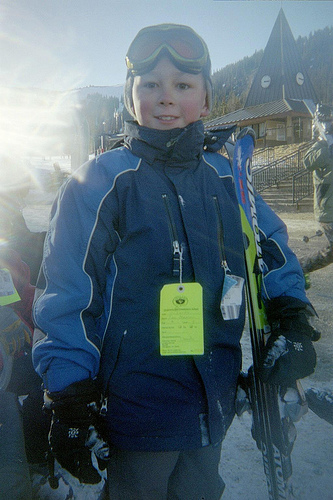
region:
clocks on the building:
[262, 71, 322, 92]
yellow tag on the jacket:
[147, 239, 212, 363]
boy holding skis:
[220, 128, 322, 419]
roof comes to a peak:
[251, 15, 327, 103]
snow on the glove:
[83, 421, 111, 459]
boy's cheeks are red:
[122, 96, 227, 124]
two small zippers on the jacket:
[159, 185, 284, 273]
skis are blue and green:
[230, 116, 278, 291]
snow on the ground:
[225, 465, 277, 492]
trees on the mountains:
[228, 53, 259, 106]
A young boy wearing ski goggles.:
[126, 31, 215, 206]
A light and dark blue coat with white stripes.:
[107, 159, 229, 270]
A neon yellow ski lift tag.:
[158, 283, 206, 361]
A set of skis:
[229, 131, 265, 315]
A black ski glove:
[52, 396, 110, 477]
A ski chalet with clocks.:
[265, 18, 305, 108]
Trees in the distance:
[222, 69, 241, 101]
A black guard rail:
[269, 152, 290, 176]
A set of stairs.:
[284, 180, 295, 209]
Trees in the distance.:
[87, 100, 114, 130]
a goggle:
[115, 9, 248, 132]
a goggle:
[99, 15, 197, 87]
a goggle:
[126, 34, 208, 92]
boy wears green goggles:
[124, 26, 194, 76]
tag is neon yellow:
[162, 275, 206, 357]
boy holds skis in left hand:
[219, 132, 308, 497]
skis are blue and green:
[233, 134, 294, 489]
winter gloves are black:
[45, 369, 111, 493]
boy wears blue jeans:
[110, 435, 210, 495]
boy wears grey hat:
[110, 56, 134, 115]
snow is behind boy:
[238, 423, 330, 498]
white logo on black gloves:
[65, 428, 80, 438]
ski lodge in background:
[217, 5, 321, 137]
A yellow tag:
[152, 249, 248, 433]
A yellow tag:
[153, 281, 202, 389]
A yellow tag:
[153, 244, 185, 368]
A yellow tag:
[163, 184, 197, 385]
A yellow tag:
[175, 297, 229, 496]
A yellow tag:
[129, 294, 205, 498]